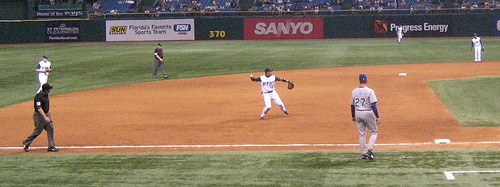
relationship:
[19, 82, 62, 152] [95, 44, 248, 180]
person on field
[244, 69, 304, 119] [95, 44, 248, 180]
player on field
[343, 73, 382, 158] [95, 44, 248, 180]
baseball player on field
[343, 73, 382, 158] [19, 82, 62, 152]
baseball player near person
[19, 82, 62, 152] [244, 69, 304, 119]
person near player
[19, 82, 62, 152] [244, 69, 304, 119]
person watching player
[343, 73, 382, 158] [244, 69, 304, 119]
baseball player near player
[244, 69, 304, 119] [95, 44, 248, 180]
player on top of field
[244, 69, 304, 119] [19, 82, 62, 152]
player near person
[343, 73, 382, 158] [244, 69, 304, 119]
baseball player watching player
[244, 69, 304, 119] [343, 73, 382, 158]
player near baseball player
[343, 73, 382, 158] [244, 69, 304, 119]
baseball player next to player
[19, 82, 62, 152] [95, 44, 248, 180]
person in field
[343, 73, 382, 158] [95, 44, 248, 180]
baseball player in field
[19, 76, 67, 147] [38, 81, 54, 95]
person wearing cap